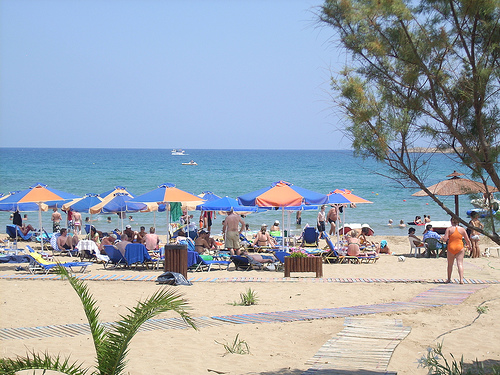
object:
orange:
[333, 188, 374, 204]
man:
[222, 209, 244, 258]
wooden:
[168, 245, 189, 269]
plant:
[288, 246, 316, 258]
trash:
[155, 271, 193, 286]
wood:
[309, 342, 405, 367]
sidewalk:
[297, 316, 410, 374]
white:
[170, 149, 189, 156]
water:
[217, 152, 282, 185]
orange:
[255, 180, 303, 207]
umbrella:
[125, 183, 207, 203]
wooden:
[35, 201, 47, 252]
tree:
[362, 33, 493, 138]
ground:
[476, 256, 499, 279]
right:
[245, 78, 303, 119]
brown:
[411, 171, 493, 197]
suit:
[447, 224, 473, 255]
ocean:
[34, 157, 124, 176]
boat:
[181, 160, 197, 166]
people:
[80, 227, 179, 260]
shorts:
[223, 223, 237, 245]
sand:
[274, 283, 311, 303]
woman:
[444, 231, 463, 279]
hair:
[451, 215, 461, 225]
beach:
[0, 236, 500, 374]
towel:
[75, 239, 111, 263]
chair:
[24, 245, 93, 275]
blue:
[96, 14, 210, 52]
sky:
[0, 0, 499, 148]